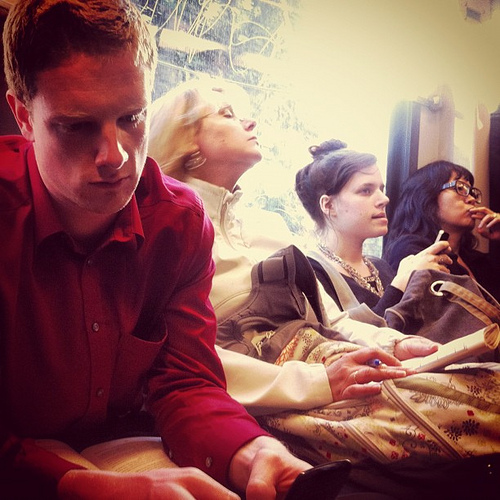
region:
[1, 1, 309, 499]
man wearing red shirt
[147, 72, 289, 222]
the woman is blonde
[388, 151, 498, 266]
woman wearing glasses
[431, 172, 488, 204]
the glasses on face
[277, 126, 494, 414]
woman holding a book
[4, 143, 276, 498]
tee shirt is red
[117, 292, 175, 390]
pocket in a red tee shirt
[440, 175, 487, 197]
a woman wearing glasses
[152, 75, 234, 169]
a woman with blonde hair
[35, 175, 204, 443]
a man wearing a red shirt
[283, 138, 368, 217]
a woman with brown hair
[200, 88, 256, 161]
a woman with her eyes closed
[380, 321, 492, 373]
a woman holding a book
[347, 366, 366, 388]
a woman wearing a ring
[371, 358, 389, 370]
blue pen in hand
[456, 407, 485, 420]
red spot on the fabric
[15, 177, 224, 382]
man wearing a red shirt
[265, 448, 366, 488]
man holding a cell phone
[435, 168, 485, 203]
stylish glasses on woman's face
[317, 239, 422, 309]
beautiful necklace around neck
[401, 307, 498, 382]
newspaper in woman's hand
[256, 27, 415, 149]
bright light in the ceiling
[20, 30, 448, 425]
these are a group of people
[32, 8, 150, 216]
the man has short hair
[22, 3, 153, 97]
the hair is brown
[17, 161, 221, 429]
the shirt is red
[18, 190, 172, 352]
the shirt has a collar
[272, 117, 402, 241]
the hair is brown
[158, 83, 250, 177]
the hair is white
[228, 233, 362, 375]
this is a backpack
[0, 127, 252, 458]
The red shirt the guy is wearing.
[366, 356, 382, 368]
The pen in the woman's hand.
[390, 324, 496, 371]
The newspaper in the woman's hand.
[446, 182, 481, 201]
The eyeglasses the woman is wearing.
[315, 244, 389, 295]
The silver necklaces around the young woman's neck.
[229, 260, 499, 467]
The designed back pack on the woman's lap.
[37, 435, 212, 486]
The book in the man's lap.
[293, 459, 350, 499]
The black phone in the man's hands.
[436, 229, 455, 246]
The phone in the young woman's hands.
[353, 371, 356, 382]
The ring on the woman's finger that is sitting next to the man.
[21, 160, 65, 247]
the collar is red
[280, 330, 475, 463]
the bag is printed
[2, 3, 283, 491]
man wearing red button down shirt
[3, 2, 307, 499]
young white adult male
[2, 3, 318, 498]
white man looking downward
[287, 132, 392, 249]
brunette with hair in bun style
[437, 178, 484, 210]
black frame glasses on woman's face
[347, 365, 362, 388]
ring on woman's finger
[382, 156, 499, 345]
woman wearing glasses with black hair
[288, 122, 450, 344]
woman wearing a blue colored shirt with brown hair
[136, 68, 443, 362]
woman wearing a yellow colored shirt with blonde hair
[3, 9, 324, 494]
man wearing a red shirt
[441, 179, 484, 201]
glasses of woman with black hair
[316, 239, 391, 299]
metal chain necklace of brown haired woman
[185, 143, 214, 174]
big circular earring of blonde woman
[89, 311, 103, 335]
single button on red colored shirt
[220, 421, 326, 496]
right hand of man wearing red shirt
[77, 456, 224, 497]
left hand of man wearing red shirt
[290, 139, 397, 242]
face of a person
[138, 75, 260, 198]
face of a person